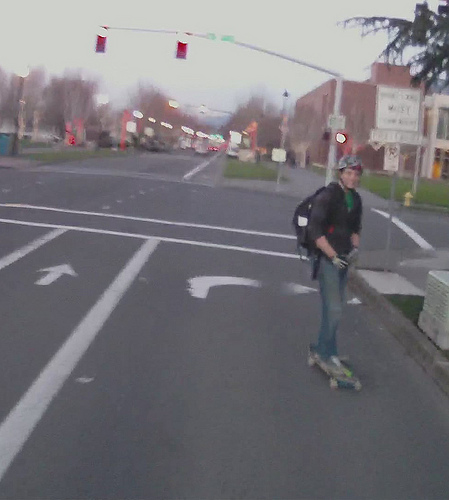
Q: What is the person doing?
A: Skateboarding.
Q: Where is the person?
A: On the street.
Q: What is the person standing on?
A: Skateboard.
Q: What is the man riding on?
A: Skateboard.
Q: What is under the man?
A: Skateboard.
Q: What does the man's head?
A: Helmet.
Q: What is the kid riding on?
A: Skateboard.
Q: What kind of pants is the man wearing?
A: Jeans.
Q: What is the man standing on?
A: Skateboard.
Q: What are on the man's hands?
A: Gloves.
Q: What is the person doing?
A: Skateboarding.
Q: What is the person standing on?
A: The skateboard.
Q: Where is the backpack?
A: On the man's back.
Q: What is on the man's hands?
A: Gloves.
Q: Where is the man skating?
A: On the road.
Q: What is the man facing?
A: The camera.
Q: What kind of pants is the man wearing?
A: Blue jeans.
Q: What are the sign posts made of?
A: Metal.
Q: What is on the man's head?
A: A helmet.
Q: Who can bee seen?
A: A boy.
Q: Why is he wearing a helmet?
A: He's skateboarding.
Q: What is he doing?
A: Skateboarding.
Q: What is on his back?
A: A backpack.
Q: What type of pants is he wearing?
A: Blue jeans.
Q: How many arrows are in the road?
A: Two.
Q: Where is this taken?
A: At a city intersection.